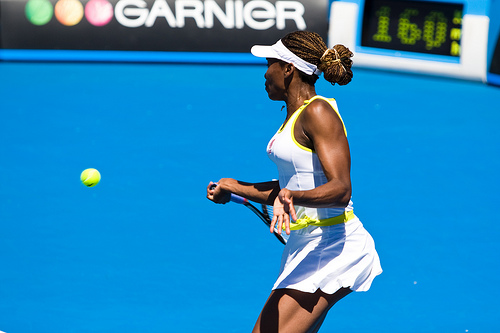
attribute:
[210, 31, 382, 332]
woman — ready to hit ball, playing tennis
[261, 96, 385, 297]
dress — white, yellow, trimmed in yellow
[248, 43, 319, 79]
hat — white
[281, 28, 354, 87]
hair — in bun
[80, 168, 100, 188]
ball — in air, yellow, green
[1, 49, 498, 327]
wall — blue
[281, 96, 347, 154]
trim — yellow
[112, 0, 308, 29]
print — white, on sign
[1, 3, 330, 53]
background — black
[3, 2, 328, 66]
billdboard sign — in background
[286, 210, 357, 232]
belt — yellow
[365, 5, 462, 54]
text — green